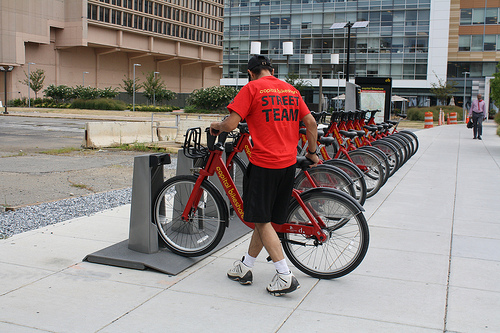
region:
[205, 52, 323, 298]
man is touching a bicycle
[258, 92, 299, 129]
black letters on shirt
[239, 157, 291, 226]
man is wearing shorts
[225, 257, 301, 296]
man's shoes are white and black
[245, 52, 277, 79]
man is wearing a hat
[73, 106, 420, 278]
the bicycles are parked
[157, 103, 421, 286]
the bicycles are red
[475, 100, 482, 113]
man wearing a tie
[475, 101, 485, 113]
the tie is red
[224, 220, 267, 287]
man's right leg in front of left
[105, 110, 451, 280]
this is where to park the bicycle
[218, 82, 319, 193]
red orange the color of the shirt he is wearing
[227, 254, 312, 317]
he wears a white rubber shoes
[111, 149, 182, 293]
this is color silver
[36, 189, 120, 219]
tiny rocks at the side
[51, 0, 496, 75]
some buildings at the background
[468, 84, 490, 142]
an old man walking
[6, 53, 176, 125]
some street lights at the park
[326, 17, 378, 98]
one solar light at the front side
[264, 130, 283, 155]
the shirt is red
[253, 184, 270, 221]
the shorts are black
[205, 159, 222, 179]
the bike is red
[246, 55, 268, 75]
he is wearing a hat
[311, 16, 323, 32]
the blind is closed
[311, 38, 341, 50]
the curtains are open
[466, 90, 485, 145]
the man is walking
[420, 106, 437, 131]
the cone is orange and white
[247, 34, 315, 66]
the lights are off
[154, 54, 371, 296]
Man returning bike to rental station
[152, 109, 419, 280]
Line of red bikes with black seats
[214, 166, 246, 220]
Yellow writing on side of red bike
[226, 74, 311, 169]
Men's red short sleeved shirt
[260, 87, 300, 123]
Writing on back of man's shirt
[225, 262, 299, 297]
White tennis shoes on man's feet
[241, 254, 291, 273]
White socks on man's feet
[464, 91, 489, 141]
Man with red tie walking down sidewalk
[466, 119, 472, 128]
Black bag in man's hand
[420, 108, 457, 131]
Orange and white striped barrels at end of sidewalk.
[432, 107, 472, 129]
Orange and white traffic cones at end of the sidewalk.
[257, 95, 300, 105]
The word 'street' in black.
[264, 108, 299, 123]
The word 'Team' in black.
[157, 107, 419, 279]
A row of red bikes with yellow letters on it.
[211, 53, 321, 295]
Man putting bike in bike rack.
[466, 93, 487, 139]
Man wearing a red tie walking down the sidewalk.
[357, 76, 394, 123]
Black display with large map in it.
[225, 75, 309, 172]
Red t-shirt worn by man.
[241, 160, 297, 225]
Black shorts worn by a man.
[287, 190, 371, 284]
A wheel on a bike.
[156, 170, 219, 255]
A wheel on a bike.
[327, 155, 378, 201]
A wheel on a bike.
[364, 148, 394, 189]
A wheel on a bike.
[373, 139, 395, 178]
A wheel on a bike.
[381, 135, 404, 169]
A wheel on a bike.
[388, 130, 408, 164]
A wheel on a bike.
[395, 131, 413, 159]
A wheel on a bike.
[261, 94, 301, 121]
Black words STREET TEAM on a red shirt back.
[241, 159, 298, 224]
Black pair of shorts on a man.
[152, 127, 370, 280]
Black and red bicycle a man is touching.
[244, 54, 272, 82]
A black cap on a mans head.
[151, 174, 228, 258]
Front black bicycle wheel a man is touching.